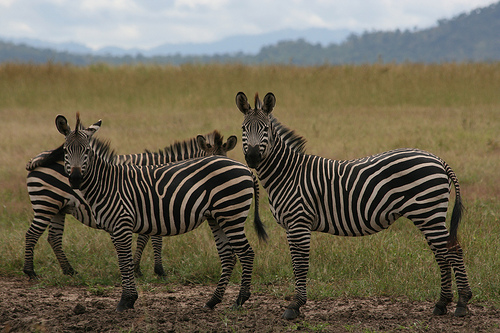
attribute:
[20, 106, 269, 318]
two zebras — looking in the same direction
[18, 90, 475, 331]
three zebras — standing in a field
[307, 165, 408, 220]
striped pattern — on a zebra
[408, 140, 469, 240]
end — rear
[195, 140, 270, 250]
end — rear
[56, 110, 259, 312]
zebra — black, white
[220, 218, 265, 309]
leg — hind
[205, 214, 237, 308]
leg — hind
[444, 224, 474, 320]
leg — hind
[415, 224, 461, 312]
leg — hind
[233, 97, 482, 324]
zebra — white, black, striped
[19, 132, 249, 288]
zebra — white, black, striped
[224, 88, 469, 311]
zebra — black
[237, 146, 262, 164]
nose — black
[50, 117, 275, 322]
zebra — white, black, striped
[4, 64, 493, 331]
plain — grassy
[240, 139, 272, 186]
nose — black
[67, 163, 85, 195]
nose — black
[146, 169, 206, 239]
stripe — black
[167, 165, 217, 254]
stripe — black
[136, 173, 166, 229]
stripe — black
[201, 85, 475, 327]
zebra — black, striped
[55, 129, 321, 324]
zebra — swinging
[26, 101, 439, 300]
zebra — standing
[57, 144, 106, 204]
nose — black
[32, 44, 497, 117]
pasture — grassy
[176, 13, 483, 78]
hillside — covered, distant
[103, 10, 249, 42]
sky — cloudy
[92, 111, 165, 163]
mane — black, white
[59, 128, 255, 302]
zebra — white, black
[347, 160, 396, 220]
stripe — black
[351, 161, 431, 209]
stripe — black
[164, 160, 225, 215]
stripe — black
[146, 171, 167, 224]
stripe — black